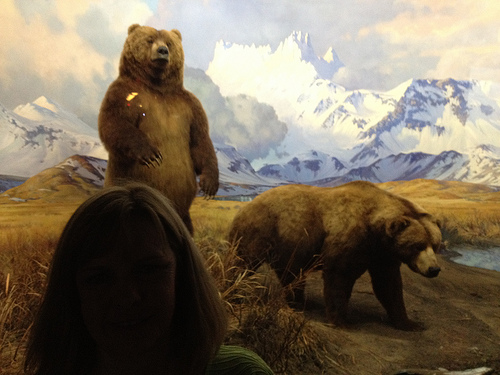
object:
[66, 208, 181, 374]
face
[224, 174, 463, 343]
statues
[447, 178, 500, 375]
ground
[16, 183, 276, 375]
woman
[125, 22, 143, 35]
ear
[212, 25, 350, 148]
mountains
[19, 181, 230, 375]
hair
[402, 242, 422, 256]
eye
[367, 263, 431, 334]
leg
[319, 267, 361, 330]
leg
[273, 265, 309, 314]
leg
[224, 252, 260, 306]
leg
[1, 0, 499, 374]
exhibit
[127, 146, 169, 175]
paw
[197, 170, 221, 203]
paw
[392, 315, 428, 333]
paw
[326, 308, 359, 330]
paw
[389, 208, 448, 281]
head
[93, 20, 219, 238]
bear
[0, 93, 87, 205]
mountain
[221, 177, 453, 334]
bear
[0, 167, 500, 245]
brown grass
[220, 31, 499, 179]
background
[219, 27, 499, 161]
distance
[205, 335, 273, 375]
shirt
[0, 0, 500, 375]
photograph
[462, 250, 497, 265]
water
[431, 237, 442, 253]
eye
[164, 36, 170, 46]
eye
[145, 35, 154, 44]
eye